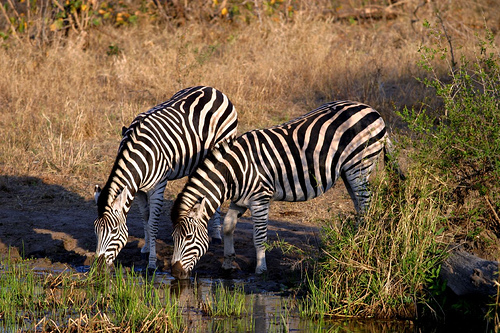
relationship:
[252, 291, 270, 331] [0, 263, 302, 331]
reflection in mud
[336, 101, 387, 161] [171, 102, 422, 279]
butt of zebra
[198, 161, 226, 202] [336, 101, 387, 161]
stripe on butt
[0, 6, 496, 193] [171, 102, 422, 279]
grass behind zebra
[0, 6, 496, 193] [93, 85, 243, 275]
grass behind zebra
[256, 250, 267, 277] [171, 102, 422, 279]
ankle of zebra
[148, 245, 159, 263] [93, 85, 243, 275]
ankle of zebra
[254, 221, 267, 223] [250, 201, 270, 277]
stripe on leg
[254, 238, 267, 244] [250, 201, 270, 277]
stripe on leg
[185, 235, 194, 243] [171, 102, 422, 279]
eye on zebra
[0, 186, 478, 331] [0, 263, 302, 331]
grass in mud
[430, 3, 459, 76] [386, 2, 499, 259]
branch on bush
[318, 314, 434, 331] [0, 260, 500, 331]
reflection in water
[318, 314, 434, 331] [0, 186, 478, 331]
reflection of grass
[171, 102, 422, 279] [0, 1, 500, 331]
zebra in meadow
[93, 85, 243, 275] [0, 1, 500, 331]
zebra in meadow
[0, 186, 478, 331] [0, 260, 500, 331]
grass near water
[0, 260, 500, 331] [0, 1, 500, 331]
water in meadow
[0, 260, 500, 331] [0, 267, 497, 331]
water in creek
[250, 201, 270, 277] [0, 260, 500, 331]
leg in water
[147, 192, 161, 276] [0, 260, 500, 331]
leg in water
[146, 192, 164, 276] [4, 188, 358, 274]
leg on ground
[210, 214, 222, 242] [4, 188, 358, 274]
leg on ground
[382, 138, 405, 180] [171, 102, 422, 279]
tail on zebra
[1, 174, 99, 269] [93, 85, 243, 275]
shadow of zebra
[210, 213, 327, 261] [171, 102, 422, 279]
shadow of zebra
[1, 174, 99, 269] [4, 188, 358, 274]
shadow on ground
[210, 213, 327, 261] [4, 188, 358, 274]
shadow on ground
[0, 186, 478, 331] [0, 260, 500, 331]
grass surrounding water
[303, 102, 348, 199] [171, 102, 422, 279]
stripe on zebra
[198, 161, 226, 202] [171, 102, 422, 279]
stripe on zebra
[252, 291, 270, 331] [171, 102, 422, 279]
reflection of zebra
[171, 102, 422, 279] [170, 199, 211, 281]
zebra has head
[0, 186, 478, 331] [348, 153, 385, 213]
grass in front of back leg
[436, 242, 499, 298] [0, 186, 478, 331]
tree trunk covered by grass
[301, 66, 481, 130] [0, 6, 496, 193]
shadow on grass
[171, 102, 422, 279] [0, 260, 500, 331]
zebra drinking water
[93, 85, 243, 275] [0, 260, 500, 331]
zebra drinking water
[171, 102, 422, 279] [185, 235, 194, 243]
zebra has left eye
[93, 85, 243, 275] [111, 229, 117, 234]
zebra has left eye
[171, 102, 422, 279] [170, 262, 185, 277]
zebra has nose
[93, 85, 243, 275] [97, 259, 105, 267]
zebra has nose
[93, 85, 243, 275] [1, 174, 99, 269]
zebra casts shadow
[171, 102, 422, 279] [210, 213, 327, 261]
zebra casts shadow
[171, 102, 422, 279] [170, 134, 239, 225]
zebra has mane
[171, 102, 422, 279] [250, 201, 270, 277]
zebra has leg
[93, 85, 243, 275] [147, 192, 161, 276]
zebra has leg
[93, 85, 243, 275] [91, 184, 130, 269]
zebra has head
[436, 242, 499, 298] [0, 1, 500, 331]
tree trunk in meadow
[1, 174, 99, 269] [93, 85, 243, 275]
shadow from zebra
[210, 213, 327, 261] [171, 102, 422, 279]
shadow from zebra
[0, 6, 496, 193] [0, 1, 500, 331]
grass in meadow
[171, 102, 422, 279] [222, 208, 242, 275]
zebra has leg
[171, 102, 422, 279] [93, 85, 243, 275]
zebra to right of zebra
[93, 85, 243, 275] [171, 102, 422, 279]
zebra to left of zebra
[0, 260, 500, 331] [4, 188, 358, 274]
water on ground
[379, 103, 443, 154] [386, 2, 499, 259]
branch on bush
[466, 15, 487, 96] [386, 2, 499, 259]
branch on bush